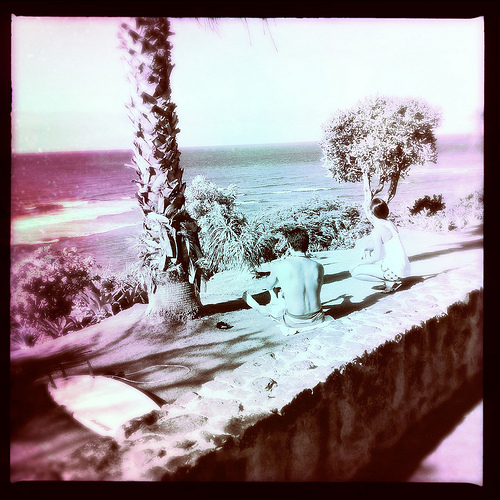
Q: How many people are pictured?
A: Two.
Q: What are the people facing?
A: The ocean.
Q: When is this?
A: Daytime.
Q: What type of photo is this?
A: Black and white.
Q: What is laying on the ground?
A: A surfboard.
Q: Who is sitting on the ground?
A: The man.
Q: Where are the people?
A: At the beach.